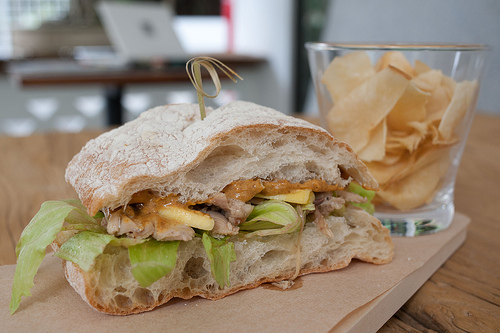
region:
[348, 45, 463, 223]
glass of potato chips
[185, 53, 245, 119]
toothpick holding a sandwich together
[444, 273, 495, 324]
brown wooden table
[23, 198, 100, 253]
lettuce leaves on a sandwich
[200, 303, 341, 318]
brown paper underneath the food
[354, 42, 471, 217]
clear glass full of chips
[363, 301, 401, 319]
wooden board on top of the table for serving the food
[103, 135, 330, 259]
two pieces of bread with meat, cheese, and lettuce in between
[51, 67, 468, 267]
chips and a sandwich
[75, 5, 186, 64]
out of focus laptop in the background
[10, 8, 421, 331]
a sandwich on a plate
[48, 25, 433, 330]
a sandwich with a toothpick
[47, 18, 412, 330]
a sandwich cut in half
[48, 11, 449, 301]
a small sandwich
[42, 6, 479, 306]
a sandwich with a sauce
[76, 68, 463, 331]
a sauce on a sandwich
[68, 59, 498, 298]
lettuce on a sandwich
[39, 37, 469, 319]
a sandwich with lettuce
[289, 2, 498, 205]
a glass with paper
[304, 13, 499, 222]
paper in a glass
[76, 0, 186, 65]
Blurry laptop most of way opened.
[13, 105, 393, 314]
Sandwich includes some green lettuce.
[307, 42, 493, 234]
A glass full of potato chips.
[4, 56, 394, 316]
Sandwich is held together by fancy toothpick.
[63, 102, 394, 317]
Two slices of bread cut from a loaf of bread.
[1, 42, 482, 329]
The sandwich and chips are sitting on a tan surface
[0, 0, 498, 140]
Entire background is blurry and not clear.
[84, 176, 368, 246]
Meat and cheese are on the sandwich.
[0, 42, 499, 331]
The lunch sits on a tan board sitting on a brown wooden surface.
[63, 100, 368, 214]
The bread has a white color on the crust.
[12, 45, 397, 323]
narrow sandwich with looped skewer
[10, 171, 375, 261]
filling of lettuce, meat, tomato and cheese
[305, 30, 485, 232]
glass filled with potato chips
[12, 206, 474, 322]
brown paper and board under sandwich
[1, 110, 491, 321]
wooden table under meal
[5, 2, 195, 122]
laptop on table in background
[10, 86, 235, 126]
heart-shaped lights under table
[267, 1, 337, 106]
triangular shape between white walls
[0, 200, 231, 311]
lettuce curling out from sandwich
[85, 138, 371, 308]
holes between layers of bread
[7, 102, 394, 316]
A mouth watering sandwich is on a table.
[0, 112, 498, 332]
A wooden table is inside a room.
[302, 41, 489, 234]
A small glass is on a piece of wood.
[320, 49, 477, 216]
Some chips are in the glass.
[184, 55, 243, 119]
A toothpick like object is in the sandwich.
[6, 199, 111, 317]
Some lettuce is sticking out the sandwich.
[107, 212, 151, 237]
A small amount of delicious meat.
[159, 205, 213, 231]
Some cheese inside the sandwich.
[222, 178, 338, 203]
Some sauce inside the sandwich.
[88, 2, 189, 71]
A laptop is in the distance.